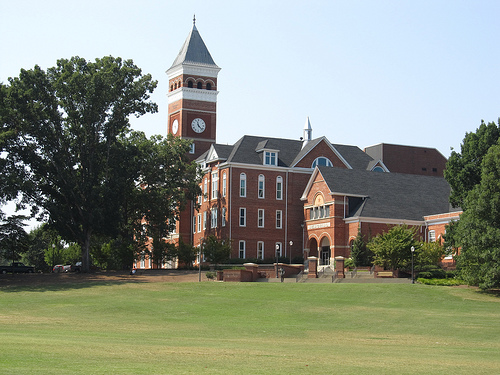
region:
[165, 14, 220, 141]
a brick steeple on the church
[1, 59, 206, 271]
a big green tree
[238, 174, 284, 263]
a group of nine windows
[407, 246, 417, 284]
a lamp post with a white shade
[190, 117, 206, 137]
an analog steeple clock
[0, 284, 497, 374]
a big green and yellow lawn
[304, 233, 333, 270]
two arched doorways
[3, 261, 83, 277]
cars parked by the big tree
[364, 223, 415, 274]
a small tree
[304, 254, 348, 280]
two brick columns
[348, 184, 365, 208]
part of a house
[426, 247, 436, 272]
part of a building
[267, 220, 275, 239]
part of a window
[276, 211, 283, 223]
part of a window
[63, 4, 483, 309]
a very dignified looking building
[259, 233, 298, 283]
outdoor lamp posts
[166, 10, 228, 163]
the clock tower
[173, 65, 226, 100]
it appears to be a bell tower as well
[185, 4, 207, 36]
a cross is at the top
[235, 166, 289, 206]
these windows are arched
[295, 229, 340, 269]
these doorways are arched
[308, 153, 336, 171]
this window is arched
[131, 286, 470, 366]
a huge wide lawn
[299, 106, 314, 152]
a steeple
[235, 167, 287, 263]
Nine windows on the side of a building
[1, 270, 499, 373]
Large green and brown lawn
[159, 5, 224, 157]
Tall clock tower attached to the building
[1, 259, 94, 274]
Row of cars under a big tree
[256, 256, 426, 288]
Steps leading to the buildng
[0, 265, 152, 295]
Shadow of a big tree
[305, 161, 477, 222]
Grey roof top on top of the building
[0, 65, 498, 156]
Clear blue cloudless sky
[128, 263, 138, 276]
One person sitting in the shade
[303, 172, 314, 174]
part of a roof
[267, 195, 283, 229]
part of a house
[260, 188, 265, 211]
part of a house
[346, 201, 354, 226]
part of a roof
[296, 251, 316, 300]
edge of a lawn